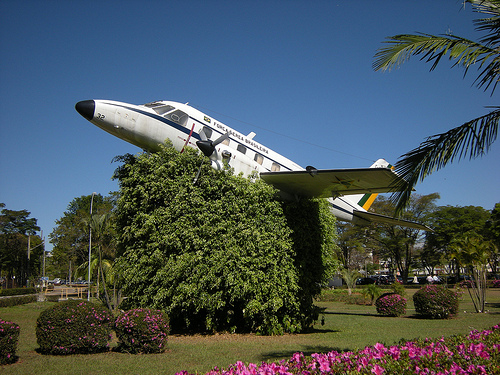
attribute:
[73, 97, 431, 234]
plane — white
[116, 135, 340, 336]
tree — green, bushy, large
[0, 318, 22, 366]
flowers — pink, purple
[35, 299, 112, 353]
flowers — pink, purple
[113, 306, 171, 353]
flowers — pink, purple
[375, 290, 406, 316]
flowers — pink, purple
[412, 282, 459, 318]
flowers — pink, purple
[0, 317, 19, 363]
bush — small, green, trimmed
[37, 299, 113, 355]
bush — small, green, trimmed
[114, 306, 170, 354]
bush — small, green, trimmed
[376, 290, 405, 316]
bush — small, green, trimmed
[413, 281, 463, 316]
bush — small, green, trimmed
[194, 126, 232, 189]
propeller — black, silver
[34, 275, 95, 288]
vehicles — parked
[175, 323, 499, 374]
flowers — small, pink, purple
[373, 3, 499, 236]
leaves — green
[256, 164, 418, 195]
wing — small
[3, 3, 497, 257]
sky — blue, clear